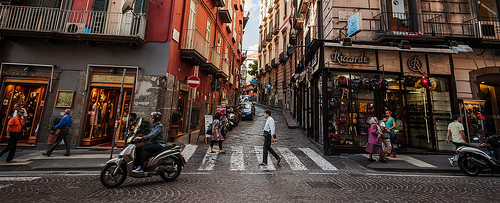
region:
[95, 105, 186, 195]
Man is riding motorcycle.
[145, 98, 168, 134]
Man is wearing a helmet.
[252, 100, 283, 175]
Man is crossing street.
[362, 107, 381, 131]
Woman's hair is covered with scarf.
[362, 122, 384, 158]
Woman is dressed in pink.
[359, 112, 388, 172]
Woman is walking on sidewalk.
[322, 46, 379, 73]
Sign on building reads Riccardo.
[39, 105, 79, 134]
Man is wearing blue shirt.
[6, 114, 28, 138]
Man is wearing orange shirt.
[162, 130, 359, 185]
Street leading into alley has dashed lines.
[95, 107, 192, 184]
person on a motor scooter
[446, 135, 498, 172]
motorbike parked on the sidewalk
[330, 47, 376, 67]
the word "Riccardo" on a building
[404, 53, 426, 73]
a letter R with a circle around it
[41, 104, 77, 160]
a man wearing a blue shirt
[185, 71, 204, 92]
a red street sign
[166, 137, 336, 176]
a crosswalk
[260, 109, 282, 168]
a man walking through the crosswalk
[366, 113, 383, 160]
a woman in a fuscia dress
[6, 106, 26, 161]
person wearing an orange shirt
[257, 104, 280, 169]
a man in a crosswalk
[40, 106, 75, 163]
a man walking on a sidewalk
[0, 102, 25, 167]
a man walking near the curb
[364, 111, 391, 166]
a person with a lavender coat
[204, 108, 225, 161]
a small person crossing the street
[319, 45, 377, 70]
the name of a new store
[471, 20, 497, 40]
an air conditioning unit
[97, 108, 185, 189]
a person riding on a motorcycle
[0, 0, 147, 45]
a second floor balcony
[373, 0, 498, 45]
a second floor balcony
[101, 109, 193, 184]
Man is riding scooter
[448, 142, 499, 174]
Parked motorcycle on curb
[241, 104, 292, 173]
Man is in crosswalk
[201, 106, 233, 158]
Woman is in crosswalk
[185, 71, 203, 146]
Red, "Do Not Enter" sign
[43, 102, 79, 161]
Man with blue shirt walking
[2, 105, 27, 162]
Man with orange shirt standing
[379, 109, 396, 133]
Woman carrying a child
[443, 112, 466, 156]
Man in white shirt walking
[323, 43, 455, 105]
Bags hanging in front of store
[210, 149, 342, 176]
wide white lines in street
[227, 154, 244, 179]
dirt on the white lines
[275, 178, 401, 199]
wavy lines on the street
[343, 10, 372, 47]
large blue sign on building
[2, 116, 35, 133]
short sleeve orange shirt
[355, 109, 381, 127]
white scarf on woman's head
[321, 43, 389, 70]
sign on front of building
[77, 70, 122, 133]
mannequins in window front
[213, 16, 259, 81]
balconies on orange building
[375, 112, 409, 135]
man wearing green shirt